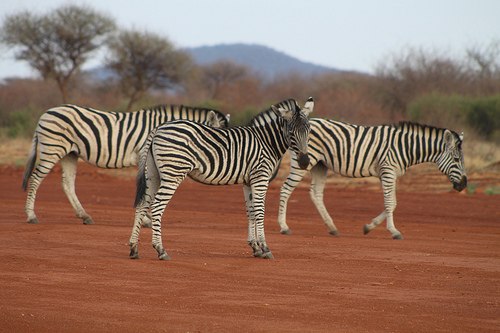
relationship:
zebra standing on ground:
[20, 102, 231, 226] [1, 162, 499, 332]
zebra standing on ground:
[127, 95, 316, 262] [1, 162, 499, 332]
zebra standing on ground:
[276, 115, 467, 241] [1, 162, 499, 332]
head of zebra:
[271, 96, 315, 174] [127, 95, 316, 262]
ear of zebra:
[270, 104, 291, 123] [127, 95, 316, 262]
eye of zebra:
[453, 156, 460, 164] [276, 115, 467, 241]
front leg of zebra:
[249, 178, 274, 259] [127, 95, 316, 262]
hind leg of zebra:
[126, 148, 159, 260] [127, 95, 316, 262]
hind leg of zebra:
[152, 159, 190, 262] [127, 95, 316, 262]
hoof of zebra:
[83, 215, 97, 227] [20, 102, 231, 226]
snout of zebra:
[298, 150, 311, 170] [127, 95, 316, 262]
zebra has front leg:
[127, 95, 316, 262] [249, 178, 274, 259]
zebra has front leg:
[127, 95, 316, 262] [244, 182, 258, 259]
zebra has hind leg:
[127, 95, 316, 262] [126, 148, 159, 260]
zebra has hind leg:
[127, 95, 316, 262] [152, 159, 190, 262]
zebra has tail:
[20, 102, 231, 226] [20, 130, 39, 189]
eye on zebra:
[453, 156, 460, 164] [276, 115, 467, 241]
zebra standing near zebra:
[127, 95, 316, 262] [276, 115, 467, 241]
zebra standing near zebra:
[127, 95, 316, 262] [20, 102, 231, 226]